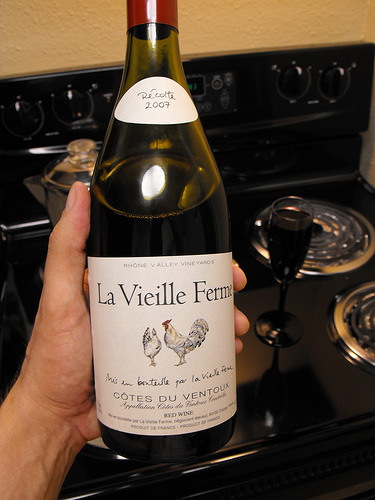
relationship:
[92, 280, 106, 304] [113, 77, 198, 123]
letter on label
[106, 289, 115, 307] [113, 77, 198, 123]
letter on label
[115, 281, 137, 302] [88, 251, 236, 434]
letter on label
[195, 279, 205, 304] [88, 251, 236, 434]
letter on label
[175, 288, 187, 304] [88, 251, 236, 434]
letter on label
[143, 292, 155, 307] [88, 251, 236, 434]
letter on label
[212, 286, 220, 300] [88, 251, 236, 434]
letter on label